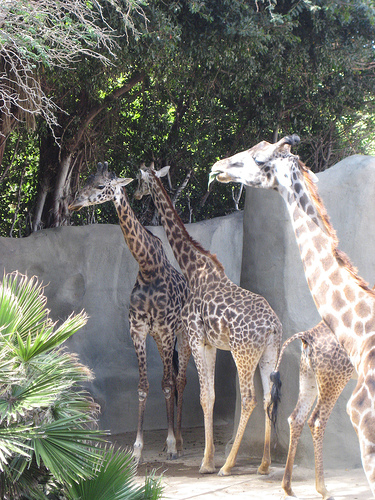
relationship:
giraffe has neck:
[203, 119, 371, 497] [264, 175, 373, 374]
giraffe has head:
[203, 119, 371, 497] [204, 115, 326, 208]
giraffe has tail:
[264, 318, 360, 499] [264, 330, 308, 437]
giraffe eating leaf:
[208, 110, 363, 261] [205, 165, 217, 185]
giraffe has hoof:
[264, 318, 360, 499] [278, 480, 293, 496]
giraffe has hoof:
[264, 318, 360, 499] [315, 481, 332, 498]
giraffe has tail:
[202, 124, 371, 498] [265, 366, 282, 430]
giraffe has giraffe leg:
[65, 171, 180, 453] [188, 350, 212, 390]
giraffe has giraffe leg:
[65, 171, 180, 453] [133, 349, 151, 394]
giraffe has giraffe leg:
[65, 171, 180, 453] [158, 342, 173, 388]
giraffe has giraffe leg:
[157, 166, 274, 476] [202, 348, 216, 382]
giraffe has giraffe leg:
[157, 166, 274, 476] [235, 364, 259, 414]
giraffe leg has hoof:
[188, 350, 212, 390] [195, 458, 219, 474]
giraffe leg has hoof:
[158, 342, 173, 388] [162, 445, 177, 463]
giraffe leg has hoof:
[133, 349, 151, 394] [129, 448, 150, 467]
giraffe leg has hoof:
[235, 364, 259, 414] [211, 467, 234, 478]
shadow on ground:
[117, 443, 273, 498] [123, 433, 349, 498]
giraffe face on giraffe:
[60, 157, 136, 214] [65, 154, 193, 479]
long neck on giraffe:
[148, 180, 194, 257] [132, 148, 283, 476]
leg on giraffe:
[186, 332, 215, 471] [132, 148, 283, 476]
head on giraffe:
[206, 135, 312, 198] [203, 119, 371, 497]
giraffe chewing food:
[203, 119, 371, 497] [205, 170, 218, 189]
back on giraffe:
[221, 275, 264, 297] [202, 124, 371, 498]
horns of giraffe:
[271, 127, 296, 159] [208, 145, 363, 401]